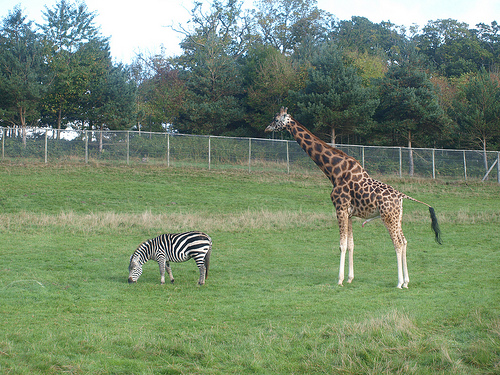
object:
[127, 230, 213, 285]
zebra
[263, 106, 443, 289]
giraffe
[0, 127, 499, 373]
enclosure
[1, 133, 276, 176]
fence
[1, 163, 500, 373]
field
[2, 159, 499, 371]
grass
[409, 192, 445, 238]
tail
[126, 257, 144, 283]
head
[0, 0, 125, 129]
trees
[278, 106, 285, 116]
horns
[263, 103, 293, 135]
head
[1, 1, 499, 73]
sky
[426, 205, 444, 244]
hair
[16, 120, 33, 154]
trunks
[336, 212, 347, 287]
leg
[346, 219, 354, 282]
leg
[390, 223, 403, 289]
leg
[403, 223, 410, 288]
leg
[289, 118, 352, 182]
neck